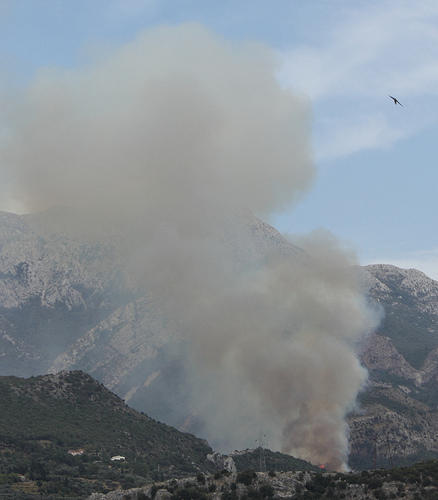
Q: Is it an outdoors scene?
A: Yes, it is outdoors.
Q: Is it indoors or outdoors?
A: It is outdoors.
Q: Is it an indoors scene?
A: No, it is outdoors.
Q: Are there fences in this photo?
A: No, there are no fences.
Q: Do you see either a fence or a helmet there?
A: No, there are no fences or helmets.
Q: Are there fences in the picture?
A: No, there are no fences.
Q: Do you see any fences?
A: No, there are no fences.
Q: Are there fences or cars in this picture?
A: No, there are no fences or cars.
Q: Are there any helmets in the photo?
A: No, there are no helmets.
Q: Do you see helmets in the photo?
A: No, there are no helmets.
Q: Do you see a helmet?
A: No, there are no helmets.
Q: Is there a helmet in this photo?
A: No, there are no helmets.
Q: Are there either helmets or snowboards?
A: No, there are no helmets or snowboards.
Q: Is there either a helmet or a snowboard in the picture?
A: No, there are no helmets or snowboards.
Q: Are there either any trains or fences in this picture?
A: No, there are no fences or trains.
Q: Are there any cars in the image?
A: No, there are no cars.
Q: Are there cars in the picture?
A: No, there are no cars.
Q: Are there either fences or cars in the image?
A: No, there are no cars or fences.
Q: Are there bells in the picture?
A: No, there are no bells.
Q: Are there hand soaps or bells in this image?
A: No, there are no bells or hand soaps.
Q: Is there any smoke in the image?
A: Yes, there is smoke.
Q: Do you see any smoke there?
A: Yes, there is smoke.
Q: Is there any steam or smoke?
A: Yes, there is smoke.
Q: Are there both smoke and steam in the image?
A: No, there is smoke but no steam.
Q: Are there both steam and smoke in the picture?
A: No, there is smoke but no steam.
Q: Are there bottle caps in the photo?
A: No, there are no bottle caps.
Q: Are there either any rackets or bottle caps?
A: No, there are no bottle caps or rackets.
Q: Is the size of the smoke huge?
A: Yes, the smoke is huge.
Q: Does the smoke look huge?
A: Yes, the smoke is huge.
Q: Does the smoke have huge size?
A: Yes, the smoke is huge.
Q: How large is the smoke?
A: The smoke is huge.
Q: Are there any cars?
A: No, there are no cars.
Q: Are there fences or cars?
A: No, there are no cars or fences.